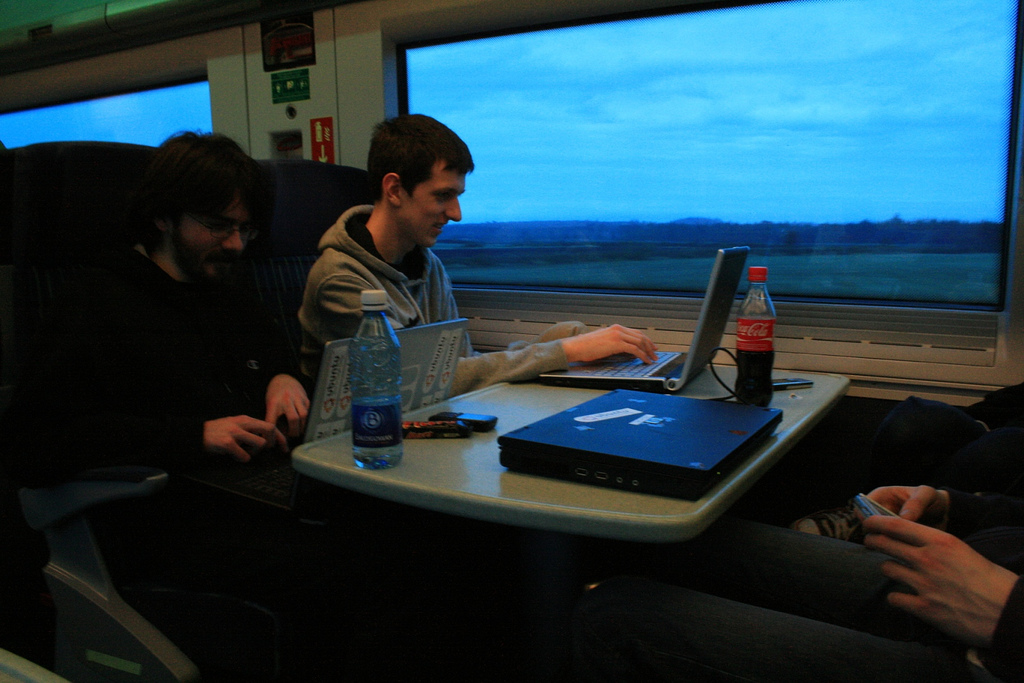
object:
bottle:
[351, 290, 403, 470]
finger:
[863, 516, 949, 546]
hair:
[367, 114, 474, 197]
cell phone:
[402, 421, 471, 439]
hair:
[129, 132, 266, 253]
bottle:
[735, 266, 773, 407]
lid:
[748, 267, 766, 281]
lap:
[165, 318, 469, 528]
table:
[291, 363, 851, 544]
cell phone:
[856, 493, 901, 518]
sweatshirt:
[0, 242, 315, 575]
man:
[0, 131, 309, 683]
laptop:
[510, 246, 750, 393]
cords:
[709, 347, 738, 401]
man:
[569, 483, 1024, 680]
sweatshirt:
[301, 205, 590, 398]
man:
[301, 115, 659, 397]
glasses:
[188, 213, 260, 239]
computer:
[497, 390, 782, 501]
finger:
[852, 533, 922, 569]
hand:
[863, 515, 1019, 652]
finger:
[884, 565, 921, 592]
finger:
[889, 593, 925, 614]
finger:
[900, 486, 934, 520]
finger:
[867, 487, 898, 502]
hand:
[855, 484, 950, 527]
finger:
[234, 423, 266, 456]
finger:
[267, 399, 280, 426]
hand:
[265, 374, 310, 437]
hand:
[562, 323, 657, 363]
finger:
[623, 341, 652, 364]